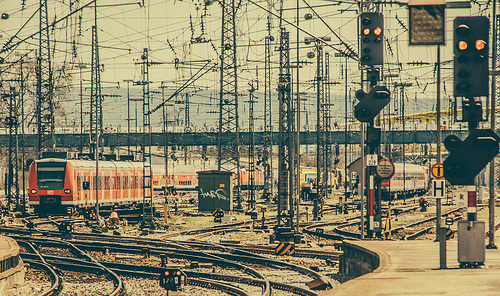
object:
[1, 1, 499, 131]
sky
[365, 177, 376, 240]
pole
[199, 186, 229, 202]
graffiti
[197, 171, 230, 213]
building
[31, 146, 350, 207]
train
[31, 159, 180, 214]
engine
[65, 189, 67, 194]
light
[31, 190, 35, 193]
light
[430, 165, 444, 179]
sign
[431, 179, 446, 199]
sign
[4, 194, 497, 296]
tracks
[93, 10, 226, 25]
line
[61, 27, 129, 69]
line